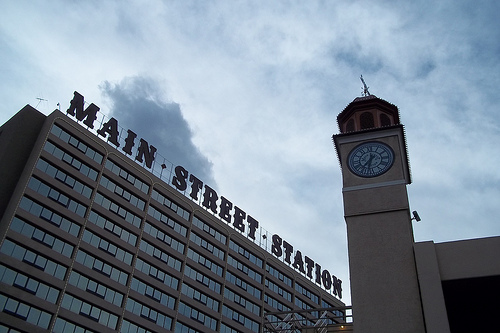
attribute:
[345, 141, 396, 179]
clock — large, blue, round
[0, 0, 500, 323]
sky — cloudy, blue, white, gray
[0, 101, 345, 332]
building — large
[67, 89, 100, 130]
letter — large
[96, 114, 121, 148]
letter — large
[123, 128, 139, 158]
letter — large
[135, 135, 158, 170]
letter — large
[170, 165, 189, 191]
letter — large